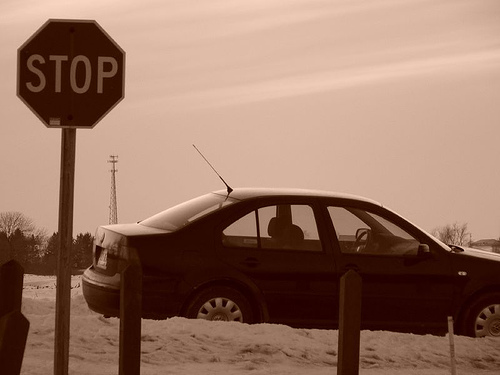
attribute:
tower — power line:
[102, 158, 126, 244]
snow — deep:
[25, 305, 499, 372]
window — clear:
[223, 200, 322, 250]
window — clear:
[327, 204, 429, 256]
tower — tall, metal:
[102, 151, 123, 223]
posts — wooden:
[106, 267, 148, 373]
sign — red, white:
[8, 10, 140, 146]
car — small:
[59, 180, 497, 374]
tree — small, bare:
[425, 220, 477, 248]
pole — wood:
[338, 266, 364, 373]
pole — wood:
[116, 258, 146, 373]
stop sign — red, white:
[15, 17, 126, 131]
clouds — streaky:
[106, 7, 491, 125]